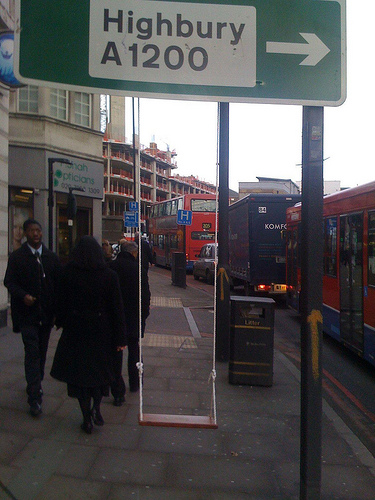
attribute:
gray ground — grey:
[188, 391, 291, 481]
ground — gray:
[13, 230, 343, 491]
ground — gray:
[3, 252, 372, 496]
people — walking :
[47, 170, 172, 397]